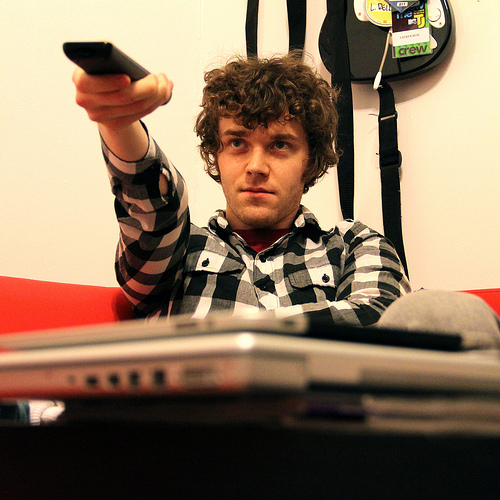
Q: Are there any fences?
A: No, there are no fences.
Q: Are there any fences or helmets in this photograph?
A: No, there are no fences or helmets.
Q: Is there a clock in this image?
A: No, there are no clocks.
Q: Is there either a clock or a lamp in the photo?
A: No, there are no clocks or lamps.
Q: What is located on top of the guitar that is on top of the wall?
A: The paper is on top of the guitar.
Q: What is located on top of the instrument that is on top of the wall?
A: The paper is on top of the guitar.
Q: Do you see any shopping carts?
A: No, there are no shopping carts.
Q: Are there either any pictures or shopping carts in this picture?
A: No, there are no shopping carts or pictures.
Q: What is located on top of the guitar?
A: The paper is on top of the guitar.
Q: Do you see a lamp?
A: No, there are no lamps.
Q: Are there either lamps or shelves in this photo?
A: No, there are no lamps or shelves.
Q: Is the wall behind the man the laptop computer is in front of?
A: Yes, the wall is behind the man.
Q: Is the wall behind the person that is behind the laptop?
A: Yes, the wall is behind the man.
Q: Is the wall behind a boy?
A: No, the wall is behind the man.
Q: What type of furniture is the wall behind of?
A: The wall is behind the couch.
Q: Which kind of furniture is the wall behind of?
A: The wall is behind the couch.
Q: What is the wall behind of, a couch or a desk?
A: The wall is behind a couch.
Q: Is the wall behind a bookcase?
A: No, the wall is behind the couch.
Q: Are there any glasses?
A: No, there are no glasses.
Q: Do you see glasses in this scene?
A: No, there are no glasses.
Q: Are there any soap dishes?
A: No, there are no soap dishes.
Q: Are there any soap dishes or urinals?
A: No, there are no soap dishes or urinals.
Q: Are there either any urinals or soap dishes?
A: No, there are no soap dishes or urinals.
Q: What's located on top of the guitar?
A: The paper is on top of the guitar.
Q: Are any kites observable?
A: No, there are no kites.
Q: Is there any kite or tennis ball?
A: No, there are no kites or tennis balls.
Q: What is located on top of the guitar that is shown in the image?
A: The paper is on top of the guitar.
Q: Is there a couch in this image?
A: Yes, there is a couch.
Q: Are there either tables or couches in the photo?
A: Yes, there is a couch.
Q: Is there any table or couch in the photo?
A: Yes, there is a couch.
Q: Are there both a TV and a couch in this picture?
A: No, there is a couch but no televisions.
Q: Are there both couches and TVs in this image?
A: No, there is a couch but no televisions.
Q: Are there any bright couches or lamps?
A: Yes, there is a bright couch.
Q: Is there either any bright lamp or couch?
A: Yes, there is a bright couch.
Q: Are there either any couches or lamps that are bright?
A: Yes, the couch is bright.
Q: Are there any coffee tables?
A: No, there are no coffee tables.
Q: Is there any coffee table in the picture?
A: No, there are no coffee tables.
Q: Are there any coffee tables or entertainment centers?
A: No, there are no coffee tables or entertainment centers.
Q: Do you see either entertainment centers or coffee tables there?
A: No, there are no coffee tables or entertainment centers.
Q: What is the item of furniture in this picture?
A: The piece of furniture is a couch.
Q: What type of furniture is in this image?
A: The furniture is a couch.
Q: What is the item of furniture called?
A: The piece of furniture is a couch.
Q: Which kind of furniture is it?
A: The piece of furniture is a couch.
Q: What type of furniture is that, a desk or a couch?
A: That is a couch.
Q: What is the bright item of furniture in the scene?
A: The piece of furniture is a couch.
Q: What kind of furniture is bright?
A: The furniture is a couch.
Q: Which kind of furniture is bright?
A: The furniture is a couch.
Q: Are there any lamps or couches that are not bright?
A: No, there is a couch but it is bright.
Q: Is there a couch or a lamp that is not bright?
A: No, there is a couch but it is bright.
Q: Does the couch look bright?
A: Yes, the couch is bright.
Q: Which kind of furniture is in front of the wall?
A: The piece of furniture is a couch.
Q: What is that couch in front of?
A: The couch is in front of the wall.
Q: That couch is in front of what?
A: The couch is in front of the wall.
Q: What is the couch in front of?
A: The couch is in front of the wall.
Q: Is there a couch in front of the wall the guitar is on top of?
A: Yes, there is a couch in front of the wall.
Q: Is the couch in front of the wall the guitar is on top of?
A: Yes, the couch is in front of the wall.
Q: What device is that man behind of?
A: The man is behind the laptop computer.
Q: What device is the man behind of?
A: The man is behind the laptop computer.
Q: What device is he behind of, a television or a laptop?
A: The man is behind a laptop.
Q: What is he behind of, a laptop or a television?
A: The man is behind a laptop.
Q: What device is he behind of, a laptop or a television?
A: The man is behind a laptop.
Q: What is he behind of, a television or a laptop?
A: The man is behind a laptop.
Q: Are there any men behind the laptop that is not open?
A: Yes, there is a man behind the laptop.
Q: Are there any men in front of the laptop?
A: No, the man is behind the laptop.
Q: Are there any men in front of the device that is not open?
A: No, the man is behind the laptop.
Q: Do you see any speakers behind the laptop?
A: No, there is a man behind the laptop.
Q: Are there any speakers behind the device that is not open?
A: No, there is a man behind the laptop.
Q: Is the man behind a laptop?
A: Yes, the man is behind a laptop.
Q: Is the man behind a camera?
A: No, the man is behind a laptop.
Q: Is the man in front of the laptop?
A: No, the man is behind the laptop.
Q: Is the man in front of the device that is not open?
A: No, the man is behind the laptop.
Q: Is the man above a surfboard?
A: No, the man is above the couch.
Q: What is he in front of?
A: The man is in front of the wall.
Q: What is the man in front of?
A: The man is in front of the wall.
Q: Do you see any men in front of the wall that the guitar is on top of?
A: Yes, there is a man in front of the wall.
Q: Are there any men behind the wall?
A: No, the man is in front of the wall.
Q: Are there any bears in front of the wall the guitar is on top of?
A: No, there is a man in front of the wall.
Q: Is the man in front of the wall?
A: Yes, the man is in front of the wall.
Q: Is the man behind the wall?
A: No, the man is in front of the wall.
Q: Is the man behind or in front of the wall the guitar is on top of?
A: The man is in front of the wall.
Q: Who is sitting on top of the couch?
A: The man is sitting on top of the couch.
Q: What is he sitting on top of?
A: The man is sitting on top of the couch.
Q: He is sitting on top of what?
A: The man is sitting on top of the couch.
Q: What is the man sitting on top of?
A: The man is sitting on top of the couch.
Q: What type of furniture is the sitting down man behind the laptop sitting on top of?
A: The man is sitting on top of the couch.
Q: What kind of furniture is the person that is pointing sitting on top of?
A: The man is sitting on top of the couch.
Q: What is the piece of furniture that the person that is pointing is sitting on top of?
A: The piece of furniture is a couch.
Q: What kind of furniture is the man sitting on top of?
A: The man is sitting on top of the couch.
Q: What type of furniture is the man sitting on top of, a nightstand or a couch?
A: The man is sitting on top of a couch.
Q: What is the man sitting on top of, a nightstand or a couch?
A: The man is sitting on top of a couch.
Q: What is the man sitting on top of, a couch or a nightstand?
A: The man is sitting on top of a couch.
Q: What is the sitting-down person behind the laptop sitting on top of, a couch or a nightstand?
A: The man is sitting on top of a couch.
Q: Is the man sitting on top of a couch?
A: Yes, the man is sitting on top of a couch.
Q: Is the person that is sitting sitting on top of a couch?
A: Yes, the man is sitting on top of a couch.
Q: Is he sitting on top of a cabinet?
A: No, the man is sitting on top of a couch.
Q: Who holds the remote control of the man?
A: The man holds the remote control.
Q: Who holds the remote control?
A: The man holds the remote control.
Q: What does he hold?
A: The man holds the remote control.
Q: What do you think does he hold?
A: The man holds the remote control.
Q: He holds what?
A: The man holds the remote control.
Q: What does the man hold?
A: The man holds the remote control.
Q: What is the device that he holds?
A: The device is a remote control.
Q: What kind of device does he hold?
A: The man holds the remote control.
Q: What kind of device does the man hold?
A: The man holds the remote control.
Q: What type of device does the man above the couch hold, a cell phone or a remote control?
A: The man holds a remote control.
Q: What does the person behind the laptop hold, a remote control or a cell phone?
A: The man holds a remote control.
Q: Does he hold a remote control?
A: Yes, the man holds a remote control.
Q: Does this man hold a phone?
A: No, the man holds a remote control.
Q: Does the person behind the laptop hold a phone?
A: No, the man holds a remote control.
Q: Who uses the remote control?
A: The man uses the remote control.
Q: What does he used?
A: The man uses a remote control.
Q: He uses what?
A: The man uses a remote control.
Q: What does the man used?
A: The man uses a remote control.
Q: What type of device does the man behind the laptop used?
A: The man uses a remote.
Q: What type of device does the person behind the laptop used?
A: The man uses a remote.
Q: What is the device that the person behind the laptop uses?
A: The device is a remote control.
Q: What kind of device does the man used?
A: The man uses a remote.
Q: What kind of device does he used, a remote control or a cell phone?
A: The man uses a remote control.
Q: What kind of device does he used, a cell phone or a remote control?
A: The man uses a remote control.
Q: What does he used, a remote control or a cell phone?
A: The man uses a remote control.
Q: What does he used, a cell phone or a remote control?
A: The man uses a remote control.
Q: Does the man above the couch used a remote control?
A: Yes, the man uses a remote control.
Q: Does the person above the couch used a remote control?
A: Yes, the man uses a remote control.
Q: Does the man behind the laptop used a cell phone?
A: No, the man uses a remote control.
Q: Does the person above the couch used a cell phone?
A: No, the man uses a remote control.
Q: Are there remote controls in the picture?
A: Yes, there is a remote control.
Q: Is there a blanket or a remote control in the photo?
A: Yes, there is a remote control.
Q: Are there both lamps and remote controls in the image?
A: No, there is a remote control but no lamps.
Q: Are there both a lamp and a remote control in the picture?
A: No, there is a remote control but no lamps.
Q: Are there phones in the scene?
A: No, there are no phones.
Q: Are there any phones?
A: No, there are no phones.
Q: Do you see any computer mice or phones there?
A: No, there are no phones or computer mice.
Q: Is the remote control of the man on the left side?
A: Yes, the remote control is on the left of the image.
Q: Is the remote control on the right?
A: No, the remote control is on the left of the image.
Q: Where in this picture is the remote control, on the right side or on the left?
A: The remote control is on the left of the image.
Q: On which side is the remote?
A: The remote is on the left of the image.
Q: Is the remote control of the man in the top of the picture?
A: Yes, the remote is in the top of the image.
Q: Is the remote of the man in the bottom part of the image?
A: No, the remote control is in the top of the image.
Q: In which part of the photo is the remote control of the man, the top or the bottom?
A: The remote control is in the top of the image.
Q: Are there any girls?
A: No, there are no girls.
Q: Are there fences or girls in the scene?
A: No, there are no girls or fences.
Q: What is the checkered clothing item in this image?
A: The clothing item is a shirt.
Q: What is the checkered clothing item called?
A: The clothing item is a shirt.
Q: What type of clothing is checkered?
A: The clothing is a shirt.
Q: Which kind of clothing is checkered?
A: The clothing is a shirt.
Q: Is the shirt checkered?
A: Yes, the shirt is checkered.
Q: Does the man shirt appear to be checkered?
A: Yes, the shirt is checkered.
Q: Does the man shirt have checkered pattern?
A: Yes, the shirt is checkered.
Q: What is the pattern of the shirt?
A: The shirt is checkered.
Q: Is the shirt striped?
A: No, the shirt is checkered.